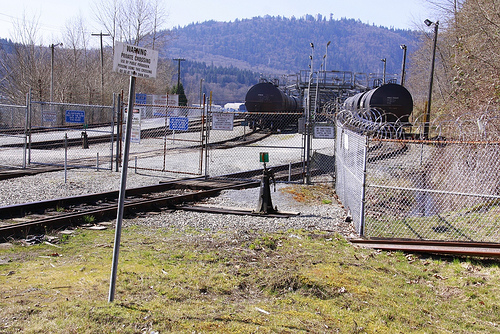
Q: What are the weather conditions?
A: It is clear.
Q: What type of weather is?
A: It is clear.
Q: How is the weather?
A: It is clear.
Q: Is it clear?
A: Yes, it is clear.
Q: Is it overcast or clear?
A: It is clear.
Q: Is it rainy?
A: No, it is clear.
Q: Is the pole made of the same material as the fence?
A: Yes, both the pole and the fence are made of metal.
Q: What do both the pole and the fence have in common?
A: The material, both the pole and the fence are metallic.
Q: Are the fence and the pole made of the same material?
A: Yes, both the fence and the pole are made of metal.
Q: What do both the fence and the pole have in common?
A: The material, both the fence and the pole are metallic.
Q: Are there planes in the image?
A: No, there are no planes.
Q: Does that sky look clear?
A: Yes, the sky is clear.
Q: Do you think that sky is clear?
A: Yes, the sky is clear.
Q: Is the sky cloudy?
A: No, the sky is clear.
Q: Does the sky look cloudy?
A: No, the sky is clear.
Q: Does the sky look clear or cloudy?
A: The sky is clear.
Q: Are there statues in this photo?
A: No, there are no statues.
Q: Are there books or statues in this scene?
A: No, there are no statues or books.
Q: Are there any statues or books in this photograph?
A: No, there are no statues or books.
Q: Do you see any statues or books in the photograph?
A: No, there are no statues or books.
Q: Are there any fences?
A: Yes, there is a fence.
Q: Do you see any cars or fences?
A: Yes, there is a fence.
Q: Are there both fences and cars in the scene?
A: Yes, there are both a fence and a car.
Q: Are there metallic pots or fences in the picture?
A: Yes, there is a metal fence.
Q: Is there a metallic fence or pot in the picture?
A: Yes, there is a metal fence.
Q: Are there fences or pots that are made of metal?
A: Yes, the fence is made of metal.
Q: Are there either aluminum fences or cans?
A: Yes, there is an aluminum fence.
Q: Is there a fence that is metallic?
A: Yes, there is a fence that is metallic.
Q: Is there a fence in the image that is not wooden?
A: Yes, there is a metallic fence.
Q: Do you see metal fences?
A: Yes, there is a fence that is made of metal.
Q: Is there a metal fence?
A: Yes, there is a fence that is made of metal.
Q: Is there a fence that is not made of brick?
A: Yes, there is a fence that is made of metal.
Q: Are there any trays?
A: No, there are no trays.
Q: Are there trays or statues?
A: No, there are no trays or statues.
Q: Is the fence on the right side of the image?
A: Yes, the fence is on the right of the image.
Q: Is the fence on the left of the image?
A: No, the fence is on the right of the image.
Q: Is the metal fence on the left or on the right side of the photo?
A: The fence is on the right of the image.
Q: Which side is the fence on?
A: The fence is on the right of the image.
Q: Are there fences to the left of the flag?
A: No, the fence is to the right of the flag.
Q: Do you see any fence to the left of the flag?
A: No, the fence is to the right of the flag.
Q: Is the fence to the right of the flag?
A: Yes, the fence is to the right of the flag.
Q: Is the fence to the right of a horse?
A: No, the fence is to the right of the flag.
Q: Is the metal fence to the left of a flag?
A: No, the fence is to the right of a flag.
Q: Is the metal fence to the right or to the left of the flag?
A: The fence is to the right of the flag.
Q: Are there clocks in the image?
A: No, there are no clocks.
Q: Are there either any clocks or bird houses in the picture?
A: No, there are no clocks or bird houses.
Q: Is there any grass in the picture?
A: Yes, there is grass.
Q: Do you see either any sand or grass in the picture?
A: Yes, there is grass.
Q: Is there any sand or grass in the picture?
A: Yes, there is grass.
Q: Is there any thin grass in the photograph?
A: Yes, there is thin grass.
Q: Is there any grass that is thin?
A: Yes, there is grass that is thin.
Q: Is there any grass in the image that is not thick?
A: Yes, there is thin grass.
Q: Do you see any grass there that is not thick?
A: Yes, there is thin grass.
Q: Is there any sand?
A: No, there is no sand.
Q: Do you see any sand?
A: No, there is no sand.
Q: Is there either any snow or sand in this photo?
A: No, there are no sand or snow.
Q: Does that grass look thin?
A: Yes, the grass is thin.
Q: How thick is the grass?
A: The grass is thin.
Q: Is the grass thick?
A: No, the grass is thin.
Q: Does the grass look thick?
A: No, the grass is thin.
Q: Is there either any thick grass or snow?
A: No, there is grass but it is thin.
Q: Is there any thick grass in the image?
A: No, there is grass but it is thin.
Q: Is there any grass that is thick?
A: No, there is grass but it is thin.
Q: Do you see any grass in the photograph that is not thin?
A: No, there is grass but it is thin.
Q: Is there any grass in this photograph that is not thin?
A: No, there is grass but it is thin.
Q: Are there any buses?
A: No, there are no buses.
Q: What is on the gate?
A: The sign is on the gate.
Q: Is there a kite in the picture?
A: No, there are no kites.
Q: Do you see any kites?
A: No, there are no kites.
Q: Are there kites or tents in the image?
A: No, there are no kites or tents.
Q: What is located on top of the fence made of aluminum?
A: The wire is on top of the fence.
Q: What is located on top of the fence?
A: The wire is on top of the fence.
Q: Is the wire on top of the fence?
A: Yes, the wire is on top of the fence.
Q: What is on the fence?
A: The wire is on the fence.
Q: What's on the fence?
A: The wire is on the fence.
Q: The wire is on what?
A: The wire is on the fence.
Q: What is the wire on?
A: The wire is on the fence.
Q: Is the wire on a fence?
A: Yes, the wire is on a fence.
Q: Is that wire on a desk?
A: No, the wire is on a fence.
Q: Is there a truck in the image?
A: No, there are no trucks.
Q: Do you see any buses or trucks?
A: No, there are no trucks or buses.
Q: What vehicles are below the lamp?
A: The vehicles are cars.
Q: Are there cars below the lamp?
A: Yes, there are cars below the lamp.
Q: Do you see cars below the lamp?
A: Yes, there are cars below the lamp.